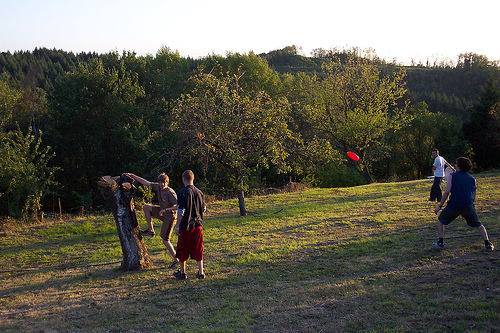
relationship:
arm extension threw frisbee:
[436, 171, 456, 212] [343, 149, 364, 163]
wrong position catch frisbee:
[123, 171, 173, 266] [343, 149, 364, 163]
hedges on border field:
[218, 161, 353, 185] [7, 164, 376, 214]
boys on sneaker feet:
[438, 155, 482, 224] [431, 239, 494, 254]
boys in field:
[439, 158, 481, 244] [0, 222, 487, 321]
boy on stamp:
[123, 171, 173, 266] [102, 170, 139, 265]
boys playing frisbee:
[439, 158, 481, 244] [343, 149, 364, 163]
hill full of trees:
[11, 50, 487, 161] [19, 76, 416, 138]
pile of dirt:
[278, 182, 312, 192] [252, 175, 314, 207]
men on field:
[140, 152, 491, 256] [0, 222, 487, 321]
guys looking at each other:
[139, 150, 206, 281] [177, 175, 221, 279]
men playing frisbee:
[140, 152, 491, 256] [343, 149, 364, 163]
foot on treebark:
[142, 205, 156, 238] [99, 173, 157, 271]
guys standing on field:
[139, 150, 206, 281] [0, 222, 487, 321]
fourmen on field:
[140, 152, 491, 256] [0, 222, 487, 321]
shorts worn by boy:
[175, 229, 208, 265] [177, 175, 221, 279]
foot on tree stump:
[142, 205, 156, 238] [102, 170, 139, 265]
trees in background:
[19, 76, 416, 138] [11, 50, 487, 161]